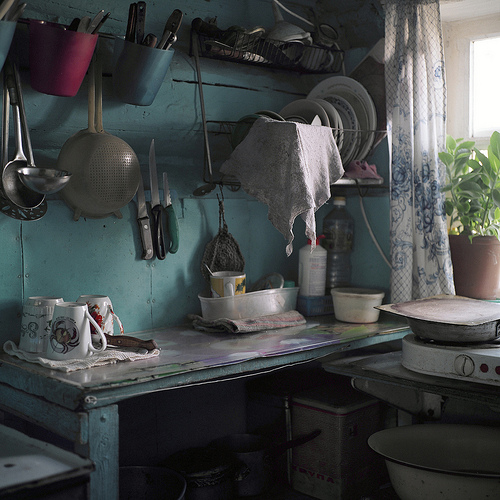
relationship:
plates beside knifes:
[230, 62, 375, 188] [129, 134, 173, 256]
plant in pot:
[424, 134, 498, 231] [443, 230, 499, 301]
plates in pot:
[230, 62, 375, 188] [443, 230, 499, 301]